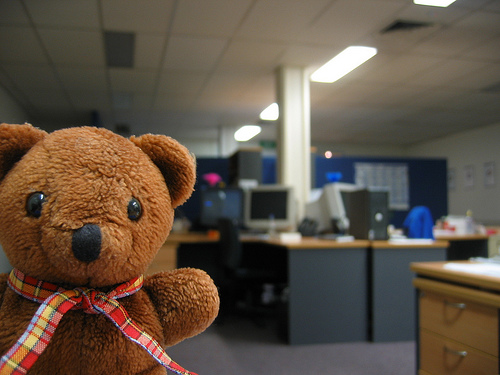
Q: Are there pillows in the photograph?
A: No, there are no pillows.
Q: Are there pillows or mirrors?
A: No, there are no pillows or mirrors.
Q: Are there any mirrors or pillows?
A: No, there are no pillows or mirrors.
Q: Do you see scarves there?
A: Yes, there is a scarf.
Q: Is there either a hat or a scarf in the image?
A: Yes, there is a scarf.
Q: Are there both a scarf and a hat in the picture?
A: No, there is a scarf but no hats.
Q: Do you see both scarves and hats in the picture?
A: No, there is a scarf but no hats.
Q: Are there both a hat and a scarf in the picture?
A: No, there is a scarf but no hats.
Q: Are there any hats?
A: No, there are no hats.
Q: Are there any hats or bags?
A: No, there are no hats or bags.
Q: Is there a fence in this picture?
A: No, there are no fences.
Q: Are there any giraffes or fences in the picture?
A: No, there are no fences or giraffes.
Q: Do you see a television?
A: No, there are no televisions.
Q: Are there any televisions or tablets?
A: No, there are no televisions or tablets.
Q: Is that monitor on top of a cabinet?
A: No, the monitor is on top of the desk.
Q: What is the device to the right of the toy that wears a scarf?
A: The device is a monitor.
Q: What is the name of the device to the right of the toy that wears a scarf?
A: The device is a monitor.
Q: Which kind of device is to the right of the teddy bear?
A: The device is a monitor.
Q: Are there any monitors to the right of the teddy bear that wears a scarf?
A: Yes, there is a monitor to the right of the teddy bear.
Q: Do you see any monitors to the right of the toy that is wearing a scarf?
A: Yes, there is a monitor to the right of the teddy bear.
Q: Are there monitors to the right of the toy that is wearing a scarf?
A: Yes, there is a monitor to the right of the teddy bear.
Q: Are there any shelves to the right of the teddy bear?
A: No, there is a monitor to the right of the teddy bear.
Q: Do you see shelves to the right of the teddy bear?
A: No, there is a monitor to the right of the teddy bear.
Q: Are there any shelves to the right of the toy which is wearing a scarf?
A: No, there is a monitor to the right of the teddy bear.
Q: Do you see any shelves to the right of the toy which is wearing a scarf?
A: No, there is a monitor to the right of the teddy bear.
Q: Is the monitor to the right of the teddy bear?
A: Yes, the monitor is to the right of the teddy bear.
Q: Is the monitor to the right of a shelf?
A: No, the monitor is to the right of the teddy bear.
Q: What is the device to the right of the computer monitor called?
A: The device is a monitor.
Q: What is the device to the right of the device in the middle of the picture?
A: The device is a monitor.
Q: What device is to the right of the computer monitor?
A: The device is a monitor.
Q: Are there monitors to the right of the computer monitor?
A: Yes, there is a monitor to the right of the computer monitor.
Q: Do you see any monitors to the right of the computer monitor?
A: Yes, there is a monitor to the right of the computer monitor.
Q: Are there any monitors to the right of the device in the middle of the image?
A: Yes, there is a monitor to the right of the computer monitor.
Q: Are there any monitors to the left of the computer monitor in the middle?
A: No, the monitor is to the right of the computer monitor.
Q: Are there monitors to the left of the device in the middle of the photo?
A: No, the monitor is to the right of the computer monitor.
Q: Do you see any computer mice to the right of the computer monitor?
A: No, there is a monitor to the right of the computer monitor.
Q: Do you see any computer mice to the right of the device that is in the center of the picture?
A: No, there is a monitor to the right of the computer monitor.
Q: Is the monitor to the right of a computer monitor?
A: Yes, the monitor is to the right of a computer monitor.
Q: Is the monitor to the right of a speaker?
A: No, the monitor is to the right of a computer monitor.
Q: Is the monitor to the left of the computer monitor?
A: No, the monitor is to the right of the computer monitor.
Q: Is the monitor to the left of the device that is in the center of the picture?
A: No, the monitor is to the right of the computer monitor.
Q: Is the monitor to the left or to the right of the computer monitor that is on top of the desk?
A: The monitor is to the right of the computer monitor.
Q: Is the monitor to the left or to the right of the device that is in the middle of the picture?
A: The monitor is to the right of the computer monitor.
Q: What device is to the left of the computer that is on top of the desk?
A: The device is a monitor.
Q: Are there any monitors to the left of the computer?
A: Yes, there is a monitor to the left of the computer.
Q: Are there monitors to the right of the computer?
A: No, the monitor is to the left of the computer.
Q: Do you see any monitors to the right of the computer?
A: No, the monitor is to the left of the computer.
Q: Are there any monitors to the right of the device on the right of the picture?
A: No, the monitor is to the left of the computer.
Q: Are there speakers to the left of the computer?
A: No, there is a monitor to the left of the computer.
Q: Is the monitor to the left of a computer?
A: Yes, the monitor is to the left of a computer.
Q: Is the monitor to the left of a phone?
A: No, the monitor is to the left of a computer.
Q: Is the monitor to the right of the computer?
A: No, the monitor is to the left of the computer.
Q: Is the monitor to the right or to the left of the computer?
A: The monitor is to the left of the computer.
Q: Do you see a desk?
A: Yes, there is a desk.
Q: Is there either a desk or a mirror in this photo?
A: Yes, there is a desk.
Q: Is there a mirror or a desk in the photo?
A: Yes, there is a desk.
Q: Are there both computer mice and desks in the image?
A: No, there is a desk but no computer mice.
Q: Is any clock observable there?
A: No, there are no clocks.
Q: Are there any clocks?
A: No, there are no clocks.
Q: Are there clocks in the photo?
A: No, there are no clocks.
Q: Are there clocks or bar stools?
A: No, there are no clocks or bar stools.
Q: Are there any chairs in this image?
A: Yes, there is a chair.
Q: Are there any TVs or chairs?
A: Yes, there is a chair.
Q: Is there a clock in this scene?
A: No, there are no clocks.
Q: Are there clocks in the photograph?
A: No, there are no clocks.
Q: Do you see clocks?
A: No, there are no clocks.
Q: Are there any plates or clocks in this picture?
A: No, there are no clocks or plates.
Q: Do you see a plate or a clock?
A: No, there are no clocks or plates.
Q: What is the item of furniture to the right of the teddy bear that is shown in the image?
A: The piece of furniture is a chair.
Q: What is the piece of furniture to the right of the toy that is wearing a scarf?
A: The piece of furniture is a chair.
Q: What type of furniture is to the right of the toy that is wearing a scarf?
A: The piece of furniture is a chair.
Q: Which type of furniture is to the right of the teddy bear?
A: The piece of furniture is a chair.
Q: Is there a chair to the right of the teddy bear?
A: Yes, there is a chair to the right of the teddy bear.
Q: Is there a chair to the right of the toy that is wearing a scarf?
A: Yes, there is a chair to the right of the teddy bear.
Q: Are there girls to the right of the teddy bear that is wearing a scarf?
A: No, there is a chair to the right of the teddy bear.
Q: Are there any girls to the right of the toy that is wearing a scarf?
A: No, there is a chair to the right of the teddy bear.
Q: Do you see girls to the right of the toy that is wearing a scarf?
A: No, there is a chair to the right of the teddy bear.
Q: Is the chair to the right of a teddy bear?
A: Yes, the chair is to the right of a teddy bear.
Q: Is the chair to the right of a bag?
A: No, the chair is to the right of a teddy bear.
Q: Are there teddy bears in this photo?
A: Yes, there is a teddy bear.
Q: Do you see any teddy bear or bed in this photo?
A: Yes, there is a teddy bear.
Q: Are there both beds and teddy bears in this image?
A: No, there is a teddy bear but no beds.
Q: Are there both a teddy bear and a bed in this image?
A: No, there is a teddy bear but no beds.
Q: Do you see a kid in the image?
A: No, there are no children.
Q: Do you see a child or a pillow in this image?
A: No, there are no children or pillows.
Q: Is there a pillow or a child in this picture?
A: No, there are no children or pillows.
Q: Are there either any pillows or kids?
A: No, there are no kids or pillows.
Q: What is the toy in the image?
A: The toy is a teddy bear.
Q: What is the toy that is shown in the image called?
A: The toy is a teddy bear.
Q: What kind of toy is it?
A: The toy is a teddy bear.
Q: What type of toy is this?
A: That is a teddy bear.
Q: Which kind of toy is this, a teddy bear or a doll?
A: That is a teddy bear.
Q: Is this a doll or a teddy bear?
A: This is a teddy bear.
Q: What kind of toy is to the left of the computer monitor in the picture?
A: The toy is a teddy bear.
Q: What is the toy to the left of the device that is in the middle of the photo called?
A: The toy is a teddy bear.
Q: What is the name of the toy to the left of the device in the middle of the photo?
A: The toy is a teddy bear.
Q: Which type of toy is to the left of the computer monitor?
A: The toy is a teddy bear.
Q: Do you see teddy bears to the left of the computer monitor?
A: Yes, there is a teddy bear to the left of the computer monitor.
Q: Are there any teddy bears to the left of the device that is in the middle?
A: Yes, there is a teddy bear to the left of the computer monitor.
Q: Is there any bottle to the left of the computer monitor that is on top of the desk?
A: No, there is a teddy bear to the left of the computer monitor.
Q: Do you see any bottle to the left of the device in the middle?
A: No, there is a teddy bear to the left of the computer monitor.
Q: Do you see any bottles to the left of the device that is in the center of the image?
A: No, there is a teddy bear to the left of the computer monitor.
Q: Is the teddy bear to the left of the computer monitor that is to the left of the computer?
A: Yes, the teddy bear is to the left of the computer monitor.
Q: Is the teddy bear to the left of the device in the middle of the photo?
A: Yes, the teddy bear is to the left of the computer monitor.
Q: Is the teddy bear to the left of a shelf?
A: No, the teddy bear is to the left of the computer monitor.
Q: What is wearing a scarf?
A: The teddy bear is wearing a scarf.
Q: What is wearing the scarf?
A: The teddy bear is wearing a scarf.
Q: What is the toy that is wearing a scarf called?
A: The toy is a teddy bear.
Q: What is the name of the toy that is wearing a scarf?
A: The toy is a teddy bear.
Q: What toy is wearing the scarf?
A: The toy is a teddy bear.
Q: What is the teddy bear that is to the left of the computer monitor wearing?
A: The teddy bear is wearing a scarf.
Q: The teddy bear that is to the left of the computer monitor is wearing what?
A: The teddy bear is wearing a scarf.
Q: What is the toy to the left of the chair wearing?
A: The teddy bear is wearing a scarf.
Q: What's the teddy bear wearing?
A: The teddy bear is wearing a scarf.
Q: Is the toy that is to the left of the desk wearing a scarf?
A: Yes, the teddy bear is wearing a scarf.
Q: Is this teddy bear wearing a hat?
A: No, the teddy bear is wearing a scarf.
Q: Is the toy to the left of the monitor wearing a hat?
A: No, the teddy bear is wearing a scarf.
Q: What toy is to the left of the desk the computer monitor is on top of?
A: The toy is a teddy bear.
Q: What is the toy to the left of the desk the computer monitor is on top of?
A: The toy is a teddy bear.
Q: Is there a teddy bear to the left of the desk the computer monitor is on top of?
A: Yes, there is a teddy bear to the left of the desk.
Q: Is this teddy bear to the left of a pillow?
A: No, the teddy bear is to the left of the desk.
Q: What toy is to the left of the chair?
A: The toy is a teddy bear.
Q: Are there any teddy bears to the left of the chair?
A: Yes, there is a teddy bear to the left of the chair.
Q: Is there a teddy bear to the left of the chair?
A: Yes, there is a teddy bear to the left of the chair.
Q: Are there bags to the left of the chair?
A: No, there is a teddy bear to the left of the chair.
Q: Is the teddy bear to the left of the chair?
A: Yes, the teddy bear is to the left of the chair.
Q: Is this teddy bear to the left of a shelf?
A: No, the teddy bear is to the left of the chair.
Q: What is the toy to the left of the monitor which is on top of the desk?
A: The toy is a teddy bear.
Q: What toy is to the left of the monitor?
A: The toy is a teddy bear.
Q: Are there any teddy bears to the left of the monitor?
A: Yes, there is a teddy bear to the left of the monitor.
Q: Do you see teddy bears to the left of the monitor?
A: Yes, there is a teddy bear to the left of the monitor.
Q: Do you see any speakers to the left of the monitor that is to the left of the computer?
A: No, there is a teddy bear to the left of the monitor.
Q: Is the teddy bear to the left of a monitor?
A: Yes, the teddy bear is to the left of a monitor.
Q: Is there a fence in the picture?
A: No, there are no fences.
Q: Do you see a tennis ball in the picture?
A: No, there are no tennis balls.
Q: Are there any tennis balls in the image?
A: No, there are no tennis balls.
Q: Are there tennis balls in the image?
A: No, there are no tennis balls.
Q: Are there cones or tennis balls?
A: No, there are no tennis balls or cones.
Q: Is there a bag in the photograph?
A: No, there are no bags.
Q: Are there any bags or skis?
A: No, there are no bags or skis.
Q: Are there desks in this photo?
A: Yes, there is a desk.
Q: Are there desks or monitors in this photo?
A: Yes, there is a desk.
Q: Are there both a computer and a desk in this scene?
A: Yes, there are both a desk and a computer.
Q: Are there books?
A: No, there are no books.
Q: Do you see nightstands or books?
A: No, there are no books or nightstands.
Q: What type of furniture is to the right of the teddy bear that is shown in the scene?
A: The piece of furniture is a desk.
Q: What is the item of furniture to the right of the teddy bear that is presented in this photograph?
A: The piece of furniture is a desk.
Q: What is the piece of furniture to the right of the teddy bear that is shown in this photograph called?
A: The piece of furniture is a desk.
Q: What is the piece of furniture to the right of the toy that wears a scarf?
A: The piece of furniture is a desk.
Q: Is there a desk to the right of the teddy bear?
A: Yes, there is a desk to the right of the teddy bear.